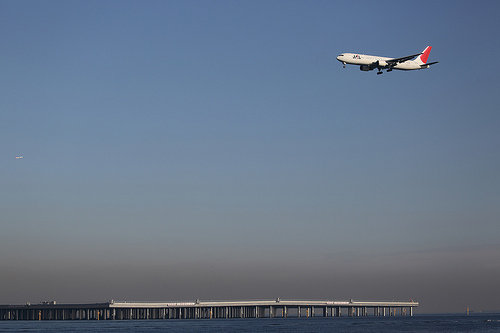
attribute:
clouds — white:
[20, 189, 96, 227]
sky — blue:
[50, 128, 209, 205]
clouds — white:
[64, 205, 487, 277]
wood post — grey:
[222, 305, 230, 320]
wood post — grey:
[236, 306, 251, 321]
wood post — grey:
[263, 302, 280, 320]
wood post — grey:
[294, 302, 302, 321]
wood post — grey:
[189, 307, 200, 318]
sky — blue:
[3, 4, 494, 313]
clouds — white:
[4, 227, 496, 298]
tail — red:
[415, 43, 435, 64]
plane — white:
[333, 40, 444, 79]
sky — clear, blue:
[4, 9, 327, 99]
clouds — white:
[135, 38, 202, 109]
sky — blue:
[15, 7, 488, 295]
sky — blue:
[99, 45, 256, 162]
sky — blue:
[3, 2, 495, 260]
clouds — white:
[198, 168, 243, 202]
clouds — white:
[105, 190, 404, 266]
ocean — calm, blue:
[0, 314, 499, 331]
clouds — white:
[151, 213, 496, 285]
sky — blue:
[39, 16, 443, 290]